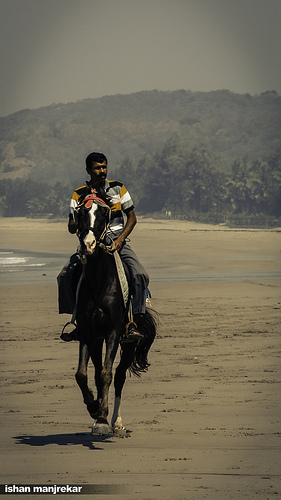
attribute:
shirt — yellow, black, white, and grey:
[67, 179, 136, 243]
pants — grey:
[102, 230, 151, 314]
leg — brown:
[90, 334, 115, 436]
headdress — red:
[76, 193, 110, 213]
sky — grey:
[0, 0, 280, 116]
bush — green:
[218, 154, 279, 216]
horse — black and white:
[67, 177, 166, 440]